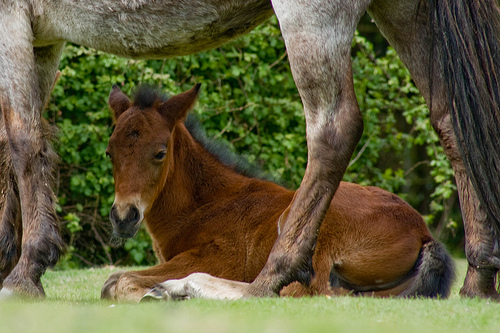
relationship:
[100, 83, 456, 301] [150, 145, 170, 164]
foal has eye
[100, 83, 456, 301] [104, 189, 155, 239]
foal has nose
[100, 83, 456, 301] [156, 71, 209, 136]
foal has ear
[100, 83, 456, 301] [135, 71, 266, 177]
foal has mane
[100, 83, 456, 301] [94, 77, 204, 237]
foal has head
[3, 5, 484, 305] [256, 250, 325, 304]
horse has hoof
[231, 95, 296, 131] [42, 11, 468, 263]
leaves on bushes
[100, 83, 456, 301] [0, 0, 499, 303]
foal sitting under horse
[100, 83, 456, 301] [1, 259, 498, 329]
foal laying in grass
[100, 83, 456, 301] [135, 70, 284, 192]
foal has mane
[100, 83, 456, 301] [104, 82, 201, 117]
foal has ears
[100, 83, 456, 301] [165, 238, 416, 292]
foal has hind leg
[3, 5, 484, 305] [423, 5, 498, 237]
horse has tail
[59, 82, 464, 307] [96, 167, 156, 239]
foal has muzzle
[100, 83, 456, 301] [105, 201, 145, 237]
foal has nose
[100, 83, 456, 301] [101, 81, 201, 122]
foal has ears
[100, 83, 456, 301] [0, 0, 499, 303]
foal under horse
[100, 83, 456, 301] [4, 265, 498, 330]
foal laying in grass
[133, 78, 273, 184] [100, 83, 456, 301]
main on foal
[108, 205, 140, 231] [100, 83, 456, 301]
nose on foal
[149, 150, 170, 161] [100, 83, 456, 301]
eye on foal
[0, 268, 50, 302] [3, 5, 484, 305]
hoof on horse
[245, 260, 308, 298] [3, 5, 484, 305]
hoof on horse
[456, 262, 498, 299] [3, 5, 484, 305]
hoof on horse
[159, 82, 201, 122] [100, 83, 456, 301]
ear on foal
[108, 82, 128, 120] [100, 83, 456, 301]
ear on foal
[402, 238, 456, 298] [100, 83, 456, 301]
tail on foal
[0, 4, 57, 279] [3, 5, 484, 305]
front leg on horse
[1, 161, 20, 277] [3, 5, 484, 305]
leg on horse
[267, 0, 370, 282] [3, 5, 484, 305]
leg on horse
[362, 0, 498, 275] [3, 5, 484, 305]
leg on horse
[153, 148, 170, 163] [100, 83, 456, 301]
eye on foal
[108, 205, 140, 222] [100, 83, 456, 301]
nose on foal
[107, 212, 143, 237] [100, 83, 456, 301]
mouth on foal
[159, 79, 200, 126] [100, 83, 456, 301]
ear on foal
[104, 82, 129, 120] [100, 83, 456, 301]
ear on foal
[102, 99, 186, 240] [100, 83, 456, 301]
face on foal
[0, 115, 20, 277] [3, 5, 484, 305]
leg on horse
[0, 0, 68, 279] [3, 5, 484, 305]
front leg of horse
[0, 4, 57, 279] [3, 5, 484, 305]
front leg of horse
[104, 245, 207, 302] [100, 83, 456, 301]
front leg of foal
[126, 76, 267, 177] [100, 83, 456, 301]
main on foal